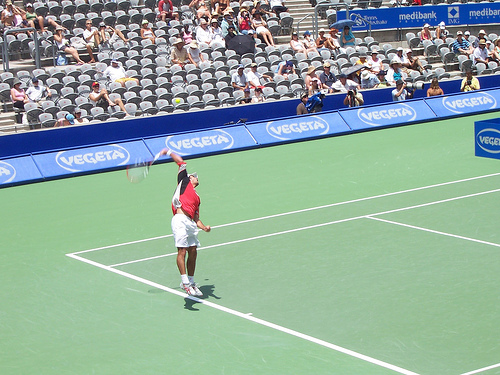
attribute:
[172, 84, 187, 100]
chair — empty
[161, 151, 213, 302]
tennis player — jumping, playing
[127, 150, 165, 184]
tennis racket — moving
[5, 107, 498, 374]
tennis court — green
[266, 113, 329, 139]
advertisement sign — vegeta, white, sponsers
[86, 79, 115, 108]
spectator — watching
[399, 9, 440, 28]
advertisement sign — medibank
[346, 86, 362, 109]
man — photographing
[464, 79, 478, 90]
shirt — white, red, black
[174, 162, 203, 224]
shirt — striped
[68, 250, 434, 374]
line — white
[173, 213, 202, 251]
shorts — white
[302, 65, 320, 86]
spectator — watching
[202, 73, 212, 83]
chair — empty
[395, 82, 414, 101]
camera man — filming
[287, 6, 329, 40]
stairs — concrete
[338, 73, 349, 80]
hat — blue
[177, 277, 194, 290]
socks — white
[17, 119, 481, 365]
court —  tennis 